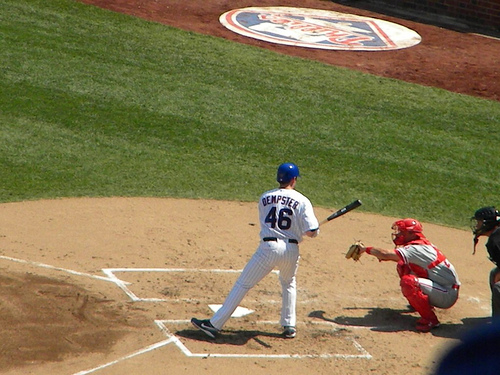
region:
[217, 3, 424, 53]
Phillies baseball team emblem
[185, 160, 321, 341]
Man with blue helmet on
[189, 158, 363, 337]
Man with Dempster written on jersey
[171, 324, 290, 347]
Shadow of a man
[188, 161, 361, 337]
Man holding a baseball bat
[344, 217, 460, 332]
Catcher wearing red helmet and pads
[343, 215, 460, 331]
Catcher holding catcher's mitt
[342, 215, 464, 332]
Catcher squatting on the ground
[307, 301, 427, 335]
Shadow of a catcher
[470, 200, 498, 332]
Umpire wearing black helmet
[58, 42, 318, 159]
The grass is short and green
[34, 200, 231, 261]
The dirt is the color beige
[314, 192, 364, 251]
The bat is the color black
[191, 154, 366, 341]
The baseball player is at the plate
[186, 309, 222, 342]
The shoe of the man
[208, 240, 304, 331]
The pants on the man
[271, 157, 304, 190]
The man has on a helmet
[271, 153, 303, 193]
The helmet is the color blue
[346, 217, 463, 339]
The catcher is on the field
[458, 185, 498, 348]
The umpire is on the field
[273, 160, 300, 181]
A blue baseball helmet.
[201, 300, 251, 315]
A white home plate.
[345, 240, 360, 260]
A brown baseball glove.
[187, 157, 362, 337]
A man about to swing a baseball bat.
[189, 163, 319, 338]
A baseball player.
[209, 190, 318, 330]
A navy blue and white baseball uniform.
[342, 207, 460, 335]
A catcher.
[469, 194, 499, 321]
An umpire.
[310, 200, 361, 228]
A baseball bat.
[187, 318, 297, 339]
White and black Nike shoes.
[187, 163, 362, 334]
a batter at home base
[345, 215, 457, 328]
a catcher behind home base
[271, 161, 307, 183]
a blue hard hat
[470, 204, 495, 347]
a umpire behind the catcher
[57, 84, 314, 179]
a green grassy field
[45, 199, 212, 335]
dirt on the field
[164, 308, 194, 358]
white lines on the field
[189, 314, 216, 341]
a blue and white shoe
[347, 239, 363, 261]
a catcher mitt on a hand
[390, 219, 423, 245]
a red mask on the catcher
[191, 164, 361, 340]
a baseball player on the home plate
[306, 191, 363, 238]
baseball player holding a bat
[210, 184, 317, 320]
baseball player wearing a white uniform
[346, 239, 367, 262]
a leather catcher's mitt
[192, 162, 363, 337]
baseball player ready to swing his bat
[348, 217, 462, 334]
a catcher ready to catch a ball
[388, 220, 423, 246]
a catcher wearing a red mask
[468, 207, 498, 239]
an umpire wearing a black mask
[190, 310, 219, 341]
a baseball player with his foot half off the ground